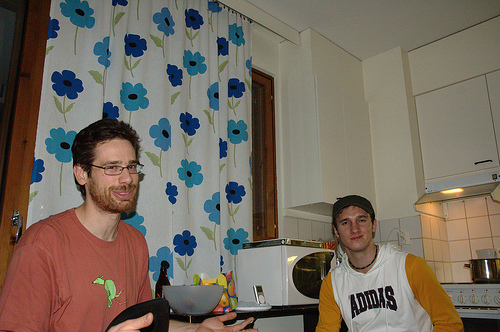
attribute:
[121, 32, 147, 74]
print — blue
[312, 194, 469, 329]
man — young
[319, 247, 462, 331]
shirt — yellow, gold, white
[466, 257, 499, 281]
pot — silver, steel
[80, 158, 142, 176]
glasses — black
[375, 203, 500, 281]
backsplash — tile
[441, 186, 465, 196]
light — on, yellow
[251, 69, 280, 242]
window — covered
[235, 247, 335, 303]
microwave — white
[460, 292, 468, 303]
dial — white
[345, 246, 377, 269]
necklace — black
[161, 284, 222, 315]
bowl — white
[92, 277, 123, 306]
dog — green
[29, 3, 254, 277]
curtain — green, white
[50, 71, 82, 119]
flower — blue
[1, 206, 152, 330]
tee shirt — red